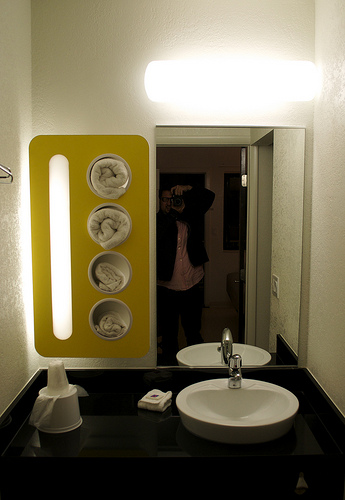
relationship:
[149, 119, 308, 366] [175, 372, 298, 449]
mirror over sink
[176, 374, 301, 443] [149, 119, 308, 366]
sink below mirror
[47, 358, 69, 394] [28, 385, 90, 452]
cup on top of dispenser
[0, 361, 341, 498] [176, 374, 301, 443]
counter surrounding sink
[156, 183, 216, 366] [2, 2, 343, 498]
man taking a picture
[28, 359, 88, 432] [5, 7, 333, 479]
dispenser in bathroom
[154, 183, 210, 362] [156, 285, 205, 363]
man wearing pants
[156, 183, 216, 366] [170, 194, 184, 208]
man holding camera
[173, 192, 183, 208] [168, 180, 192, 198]
camera in hands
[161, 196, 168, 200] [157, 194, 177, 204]
lens for eyeglasses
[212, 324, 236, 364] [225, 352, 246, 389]
reflection of tap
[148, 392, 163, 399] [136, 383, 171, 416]
soap on towel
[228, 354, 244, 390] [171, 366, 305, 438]
faucet on sink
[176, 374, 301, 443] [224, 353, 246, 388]
sink under faucet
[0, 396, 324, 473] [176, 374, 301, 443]
counter next to sink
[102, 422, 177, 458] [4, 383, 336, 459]
reflection on counter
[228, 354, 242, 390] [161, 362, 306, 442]
faucet on a sink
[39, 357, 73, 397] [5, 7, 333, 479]
cup in bathroom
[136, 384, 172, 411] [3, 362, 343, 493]
towel in bathroom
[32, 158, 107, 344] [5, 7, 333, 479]
lamp in bathroom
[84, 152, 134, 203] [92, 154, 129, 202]
hole for towel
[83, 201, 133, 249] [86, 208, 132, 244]
hole for towel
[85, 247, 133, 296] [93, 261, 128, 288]
hole for towel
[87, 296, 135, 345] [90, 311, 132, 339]
hole for towel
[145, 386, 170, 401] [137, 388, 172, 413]
soap on towel